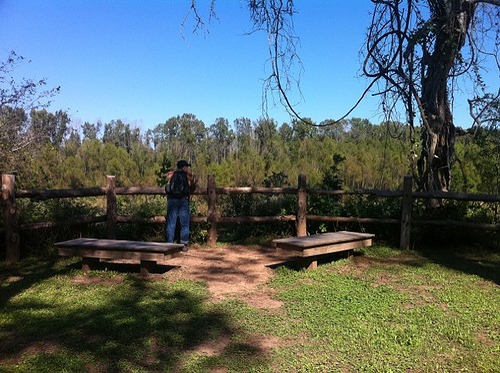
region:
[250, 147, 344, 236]
brown and wooden fence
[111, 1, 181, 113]
blue and clear sky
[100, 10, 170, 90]
no clouds in sky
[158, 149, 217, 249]
A man on the fence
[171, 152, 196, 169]
A black cap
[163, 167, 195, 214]
A black backpack on the back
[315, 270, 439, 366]
Grass on the field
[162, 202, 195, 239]
A pair of blue jeans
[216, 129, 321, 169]
Trees in the forest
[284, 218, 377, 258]
Wooden bench in the park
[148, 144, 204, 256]
A man standing alone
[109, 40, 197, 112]
Clear blue skies in the background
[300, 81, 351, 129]
white clouds in blue sky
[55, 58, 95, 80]
white clouds in blue sky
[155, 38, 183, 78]
white clouds in blue sky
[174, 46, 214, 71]
white clouds in blue sky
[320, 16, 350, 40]
white clouds in blue sky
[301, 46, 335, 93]
white clouds in blue sky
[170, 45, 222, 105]
white clouds in blue sky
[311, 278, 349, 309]
short green grass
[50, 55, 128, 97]
white clouds in blue sky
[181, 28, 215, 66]
white clouds in blue sky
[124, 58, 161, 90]
white clouds in blue sky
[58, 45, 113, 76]
white clouds in blue sky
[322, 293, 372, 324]
short green gras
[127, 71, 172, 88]
white clouds in blue sky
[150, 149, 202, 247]
woman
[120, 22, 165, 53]
white clouds in blue sky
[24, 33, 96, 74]
white clouds in blue sky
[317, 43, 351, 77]
white clouds in blue sky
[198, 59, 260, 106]
white clouds in blue sky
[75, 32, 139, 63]
white clouds in blue sky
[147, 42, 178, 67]
white clouds in blue sky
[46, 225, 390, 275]
a pair of benches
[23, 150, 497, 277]
a brown wood fence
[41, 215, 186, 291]
the bench is brown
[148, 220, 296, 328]
a patch of dirt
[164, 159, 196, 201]
man has a backpack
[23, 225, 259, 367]
shadows on the ground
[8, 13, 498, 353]
a bright and clear day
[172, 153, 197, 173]
man is wearing a hat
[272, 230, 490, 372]
a patch of grass